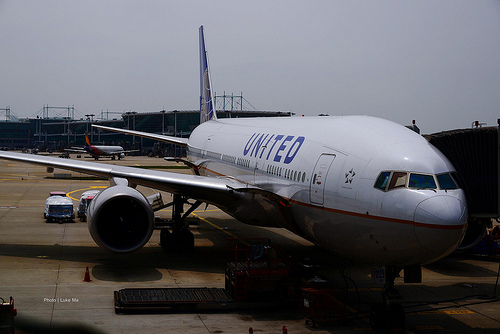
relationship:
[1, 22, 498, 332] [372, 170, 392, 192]
plane has window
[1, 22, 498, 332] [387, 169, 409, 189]
plane has window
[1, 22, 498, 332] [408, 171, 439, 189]
plane has window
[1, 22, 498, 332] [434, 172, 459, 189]
plane has window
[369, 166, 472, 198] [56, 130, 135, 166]
windshield on airplane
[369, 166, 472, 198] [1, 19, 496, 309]
windshield on airplane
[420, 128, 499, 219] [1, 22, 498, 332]
tunnel going into plane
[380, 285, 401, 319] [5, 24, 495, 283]
wheels of plane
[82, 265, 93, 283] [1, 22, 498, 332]
cone under plane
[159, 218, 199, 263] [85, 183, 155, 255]
wheels near engine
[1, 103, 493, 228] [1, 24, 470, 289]
building behind aircraft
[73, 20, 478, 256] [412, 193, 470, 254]
aircraft with nose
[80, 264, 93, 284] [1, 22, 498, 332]
cone beside plane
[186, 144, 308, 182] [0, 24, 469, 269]
windows of plane